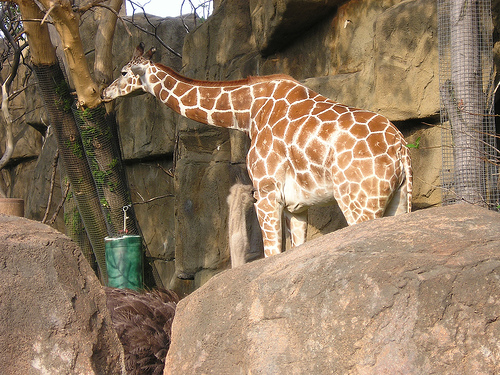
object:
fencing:
[448, 0, 493, 203]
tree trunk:
[447, 0, 489, 198]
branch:
[1, 0, 23, 198]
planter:
[1, 195, 25, 220]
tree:
[12, 0, 171, 297]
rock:
[0, 214, 123, 374]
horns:
[131, 38, 162, 60]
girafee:
[99, 47, 415, 258]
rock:
[313, 17, 467, 117]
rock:
[191, 21, 260, 87]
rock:
[170, 129, 257, 264]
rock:
[33, 32, 100, 219]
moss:
[72, 103, 129, 203]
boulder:
[165, 203, 499, 374]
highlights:
[247, 290, 311, 365]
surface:
[164, 197, 500, 375]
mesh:
[14, 56, 163, 294]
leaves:
[72, 155, 127, 217]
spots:
[290, 97, 314, 118]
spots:
[336, 112, 355, 127]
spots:
[335, 133, 353, 148]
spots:
[352, 157, 373, 177]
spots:
[368, 133, 385, 150]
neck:
[149, 64, 255, 132]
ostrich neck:
[226, 195, 251, 263]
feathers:
[103, 286, 185, 374]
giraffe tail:
[402, 144, 418, 216]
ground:
[310, 83, 377, 128]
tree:
[439, 0, 496, 208]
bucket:
[101, 233, 147, 291]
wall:
[317, 13, 449, 115]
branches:
[128, 0, 218, 48]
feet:
[339, 199, 389, 227]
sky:
[119, 0, 214, 22]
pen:
[0, 0, 500, 368]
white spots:
[309, 145, 320, 157]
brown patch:
[285, 146, 309, 173]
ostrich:
[93, 284, 187, 375]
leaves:
[65, 101, 112, 134]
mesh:
[436, 0, 500, 218]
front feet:
[251, 181, 296, 259]